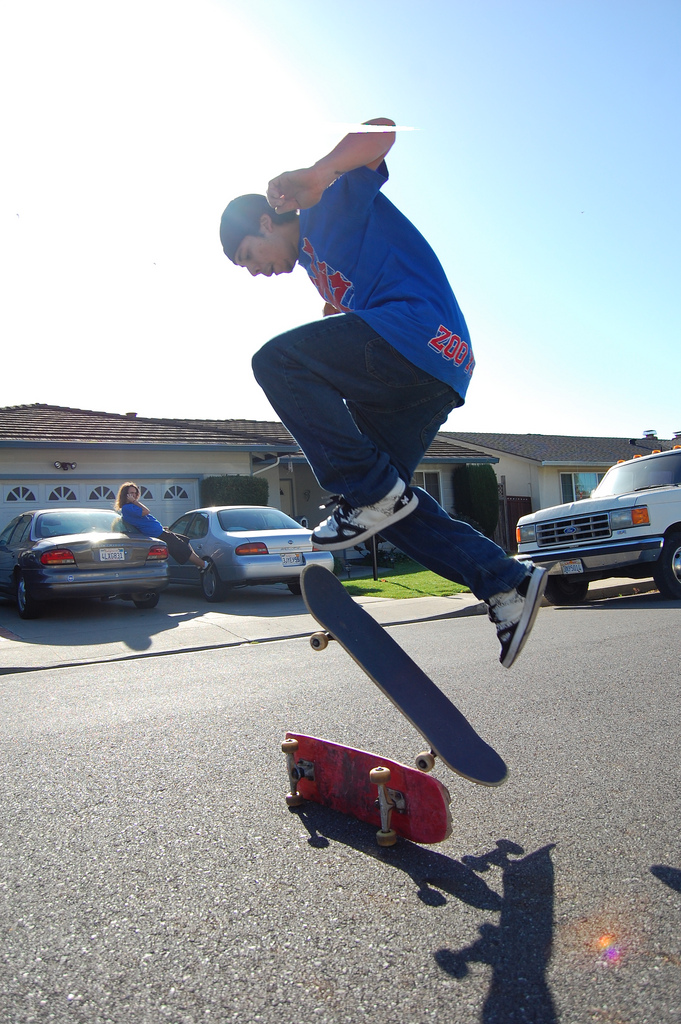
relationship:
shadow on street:
[288, 800, 559, 1024] [0, 579, 681, 1019]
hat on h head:
[212, 189, 296, 248] [212, 182, 316, 286]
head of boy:
[212, 182, 316, 286] [212, 113, 558, 670]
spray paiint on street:
[548, 883, 661, 987] [8, 628, 679, 1021]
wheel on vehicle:
[11, 566, 45, 622] [4, 504, 184, 617]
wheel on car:
[187, 554, 226, 606] [169, 506, 335, 604]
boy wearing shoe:
[220, 117, 548, 668] [489, 558, 550, 669]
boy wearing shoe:
[220, 117, 548, 668] [306, 479, 424, 560]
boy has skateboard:
[220, 117, 548, 668] [271, 557, 512, 856]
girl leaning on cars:
[110, 480, 215, 575] [2, 494, 335, 625]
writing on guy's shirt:
[290, 232, 356, 312] [277, 164, 475, 405]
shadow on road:
[296, 813, 567, 1022] [4, 580, 678, 1022]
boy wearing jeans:
[220, 117, 548, 668] [247, 307, 511, 597]